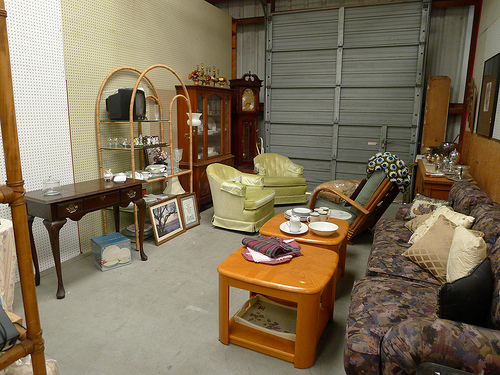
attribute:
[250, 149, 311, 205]
recliner — yellow, leather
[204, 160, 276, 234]
recliner — leather, yellow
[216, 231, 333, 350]
table — small, wooden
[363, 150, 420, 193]
afghan — blue, white, brown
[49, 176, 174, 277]
desk — cherry wood, queen anne style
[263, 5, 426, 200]
garage door — large, metallic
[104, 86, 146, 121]
tv — black, small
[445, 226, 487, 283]
pillow — tan, brown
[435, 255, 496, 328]
pillow — tan, brown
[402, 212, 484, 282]
pillow — tan, brown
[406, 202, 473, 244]
pillow — tan, brown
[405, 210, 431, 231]
pillow — tan, brown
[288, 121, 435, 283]
chair — antique, reclining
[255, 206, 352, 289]
wooden table — small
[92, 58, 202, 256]
shelf — wicker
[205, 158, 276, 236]
chair — green, upholstered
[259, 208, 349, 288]
table — light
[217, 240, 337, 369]
table — light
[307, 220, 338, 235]
bowl — white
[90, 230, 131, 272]
box — blue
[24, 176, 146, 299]
table — small, wooden